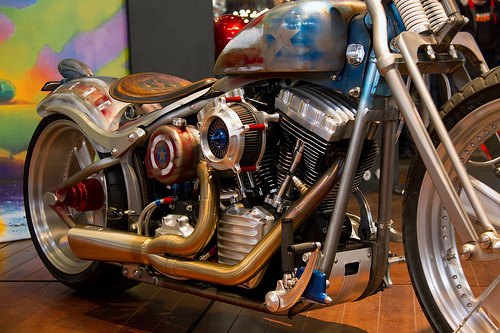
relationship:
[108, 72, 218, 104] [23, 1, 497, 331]
seat on chopper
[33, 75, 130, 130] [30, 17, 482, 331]
wheel cover on motorcycle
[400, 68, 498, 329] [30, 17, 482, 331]
tire on motorcycle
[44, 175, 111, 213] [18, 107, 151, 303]
joint on tire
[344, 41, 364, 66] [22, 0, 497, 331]
bolt on bike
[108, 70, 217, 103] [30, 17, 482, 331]
seat on motorcycle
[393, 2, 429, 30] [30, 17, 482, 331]
spring on motorcycle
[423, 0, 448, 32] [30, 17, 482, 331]
spring on motorcycle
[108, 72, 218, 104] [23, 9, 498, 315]
seat of motorcycle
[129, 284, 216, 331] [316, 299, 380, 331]
shadow on ground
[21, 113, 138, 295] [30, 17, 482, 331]
wheel on motorcycle